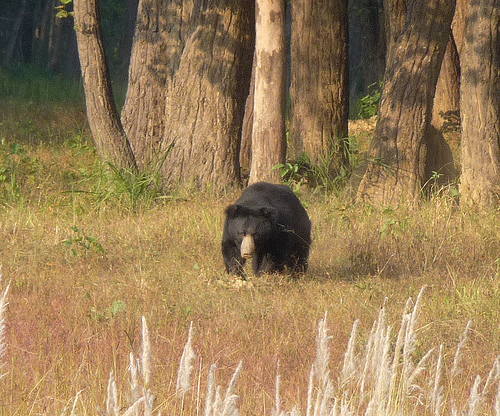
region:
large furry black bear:
[218, 176, 318, 285]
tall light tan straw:
[102, 281, 497, 413]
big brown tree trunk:
[120, 0, 242, 190]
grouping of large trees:
[45, 1, 499, 215]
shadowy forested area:
[1, 0, 136, 121]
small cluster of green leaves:
[270, 136, 367, 201]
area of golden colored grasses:
[2, 188, 499, 414]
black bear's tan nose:
[240, 233, 258, 260]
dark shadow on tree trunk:
[434, 105, 464, 136]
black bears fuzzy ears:
[222, 200, 283, 222]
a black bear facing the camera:
[215, 179, 315, 280]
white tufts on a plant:
[168, 320, 196, 405]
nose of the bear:
[235, 235, 252, 261]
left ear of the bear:
[257, 204, 275, 216]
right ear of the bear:
[220, 201, 245, 221]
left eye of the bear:
[250, 227, 261, 242]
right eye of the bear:
[236, 224, 249, 241]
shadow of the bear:
[305, 261, 403, 284]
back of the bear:
[230, 182, 300, 205]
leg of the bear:
[225, 258, 242, 280]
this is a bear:
[207, 180, 313, 285]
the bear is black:
[216, 176, 315, 285]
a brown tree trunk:
[67, 2, 139, 193]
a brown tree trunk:
[118, 0, 208, 170]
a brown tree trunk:
[166, 0, 246, 186]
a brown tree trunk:
[238, 0, 292, 179]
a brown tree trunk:
[293, 0, 353, 164]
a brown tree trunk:
[359, 4, 437, 210]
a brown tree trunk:
[453, 2, 498, 204]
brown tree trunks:
[63, 0, 499, 221]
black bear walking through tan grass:
[126, 142, 352, 299]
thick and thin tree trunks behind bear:
[70, 21, 486, 186]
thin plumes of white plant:
[77, 287, 457, 398]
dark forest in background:
[5, 0, 120, 115]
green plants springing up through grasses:
[6, 85, 441, 290]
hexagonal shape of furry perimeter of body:
[205, 155, 315, 285]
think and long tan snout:
[232, 225, 262, 265]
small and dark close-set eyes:
[231, 221, 261, 241]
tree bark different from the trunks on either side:
[185, 10, 345, 155]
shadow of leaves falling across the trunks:
[102, 5, 488, 100]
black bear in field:
[206, 169, 334, 304]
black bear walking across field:
[175, 142, 350, 319]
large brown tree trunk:
[167, 0, 254, 177]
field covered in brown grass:
[15, 289, 115, 414]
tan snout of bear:
[235, 228, 262, 260]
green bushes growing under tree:
[75, 147, 178, 210]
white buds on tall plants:
[301, 285, 443, 414]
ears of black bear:
[221, 199, 277, 219]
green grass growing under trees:
[11, 67, 78, 104]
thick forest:
[1, 0, 73, 60]